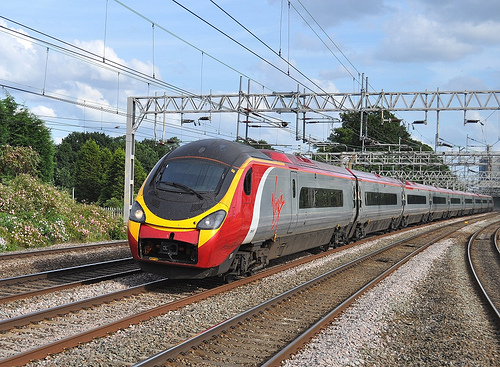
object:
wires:
[1, 1, 439, 179]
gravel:
[0, 208, 495, 365]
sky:
[0, 1, 498, 189]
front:
[128, 135, 275, 273]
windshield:
[146, 154, 226, 219]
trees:
[0, 88, 188, 221]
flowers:
[0, 145, 131, 248]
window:
[299, 185, 345, 209]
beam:
[126, 89, 499, 116]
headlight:
[131, 201, 147, 222]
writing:
[270, 174, 285, 236]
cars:
[348, 168, 496, 235]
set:
[0, 208, 495, 365]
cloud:
[0, 18, 163, 129]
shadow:
[34, 246, 225, 296]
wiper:
[156, 181, 206, 200]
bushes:
[0, 145, 127, 248]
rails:
[0, 212, 498, 362]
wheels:
[230, 246, 266, 279]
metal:
[128, 90, 499, 195]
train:
[129, 138, 495, 283]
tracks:
[0, 274, 218, 363]